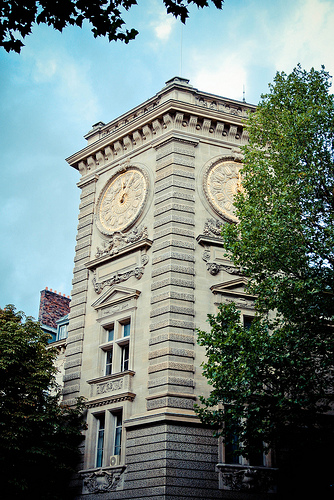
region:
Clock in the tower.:
[93, 160, 151, 236]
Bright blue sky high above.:
[15, 93, 48, 198]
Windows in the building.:
[90, 314, 135, 375]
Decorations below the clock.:
[82, 224, 155, 288]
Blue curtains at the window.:
[94, 415, 106, 469]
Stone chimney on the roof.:
[32, 280, 72, 330]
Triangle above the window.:
[91, 277, 141, 316]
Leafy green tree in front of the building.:
[191, 210, 328, 478]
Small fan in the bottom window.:
[99, 446, 119, 471]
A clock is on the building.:
[90, 165, 147, 235]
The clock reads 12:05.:
[116, 172, 133, 202]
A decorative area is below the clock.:
[85, 228, 149, 292]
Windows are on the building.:
[99, 315, 131, 375]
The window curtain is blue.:
[95, 429, 105, 467]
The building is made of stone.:
[149, 262, 193, 322]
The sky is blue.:
[99, 60, 145, 89]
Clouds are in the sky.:
[197, 54, 244, 83]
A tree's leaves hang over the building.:
[0, 0, 222, 56]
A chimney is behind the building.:
[39, 287, 68, 311]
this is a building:
[39, 95, 310, 491]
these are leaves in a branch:
[216, 385, 283, 441]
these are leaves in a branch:
[32, 407, 70, 469]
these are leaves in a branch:
[2, 325, 40, 378]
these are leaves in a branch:
[224, 318, 271, 380]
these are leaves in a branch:
[287, 349, 326, 426]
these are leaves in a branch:
[21, 396, 59, 450]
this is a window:
[99, 344, 113, 370]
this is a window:
[117, 340, 136, 379]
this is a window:
[89, 414, 114, 471]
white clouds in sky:
[4, 1, 332, 298]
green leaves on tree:
[196, 62, 331, 459]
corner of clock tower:
[66, 76, 295, 496]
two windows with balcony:
[89, 312, 135, 396]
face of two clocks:
[96, 155, 261, 236]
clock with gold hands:
[101, 170, 144, 228]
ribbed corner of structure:
[152, 143, 194, 402]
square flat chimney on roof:
[34, 289, 70, 339]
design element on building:
[80, 465, 127, 491]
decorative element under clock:
[86, 225, 154, 291]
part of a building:
[207, 407, 235, 415]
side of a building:
[166, 469, 172, 474]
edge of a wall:
[182, 439, 188, 450]